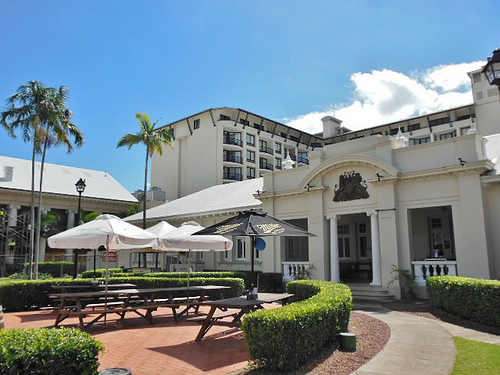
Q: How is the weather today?
A: It is clear.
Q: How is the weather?
A: It is clear.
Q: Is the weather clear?
A: Yes, it is clear.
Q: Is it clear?
A: Yes, it is clear.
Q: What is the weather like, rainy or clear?
A: It is clear.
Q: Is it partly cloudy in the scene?
A: No, it is clear.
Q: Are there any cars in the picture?
A: No, there are no cars.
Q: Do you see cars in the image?
A: No, there are no cars.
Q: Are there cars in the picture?
A: No, there are no cars.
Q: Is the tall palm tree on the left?
A: Yes, the palm is on the left of the image.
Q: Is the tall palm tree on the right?
A: No, the palm is on the left of the image.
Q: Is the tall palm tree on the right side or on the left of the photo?
A: The palm tree is on the left of the image.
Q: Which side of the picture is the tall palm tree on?
A: The palm is on the left of the image.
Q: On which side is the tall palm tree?
A: The palm is on the left of the image.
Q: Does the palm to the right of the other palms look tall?
A: Yes, the palm is tall.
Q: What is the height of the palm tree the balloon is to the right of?
A: The palm tree is tall.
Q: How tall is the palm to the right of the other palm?
A: The palm tree is tall.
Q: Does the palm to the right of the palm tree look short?
A: No, the palm is tall.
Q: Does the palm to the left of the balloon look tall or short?
A: The palm is tall.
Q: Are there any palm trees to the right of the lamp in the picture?
A: Yes, there is a palm tree to the right of the lamp.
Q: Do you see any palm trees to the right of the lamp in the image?
A: Yes, there is a palm tree to the right of the lamp.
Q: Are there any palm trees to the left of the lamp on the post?
A: No, the palm tree is to the right of the lamp.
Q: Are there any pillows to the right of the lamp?
A: No, there is a palm tree to the right of the lamp.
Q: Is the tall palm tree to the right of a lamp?
A: Yes, the palm is to the right of a lamp.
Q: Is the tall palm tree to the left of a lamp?
A: No, the palm is to the right of a lamp.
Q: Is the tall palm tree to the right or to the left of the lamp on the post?
A: The palm is to the right of the lamp.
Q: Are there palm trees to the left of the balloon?
A: Yes, there is a palm tree to the left of the balloon.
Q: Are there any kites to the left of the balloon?
A: No, there is a palm tree to the left of the balloon.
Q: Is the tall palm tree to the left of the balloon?
A: Yes, the palm is to the left of the balloon.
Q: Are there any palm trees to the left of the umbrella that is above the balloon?
A: Yes, there is a palm tree to the left of the umbrella.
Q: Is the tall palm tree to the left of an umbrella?
A: Yes, the palm tree is to the left of an umbrella.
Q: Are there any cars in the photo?
A: No, there are no cars.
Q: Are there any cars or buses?
A: No, there are no cars or buses.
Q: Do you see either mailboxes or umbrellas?
A: Yes, there is an umbrella.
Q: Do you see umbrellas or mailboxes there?
A: Yes, there is an umbrella.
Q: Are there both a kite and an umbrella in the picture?
A: No, there is an umbrella but no kites.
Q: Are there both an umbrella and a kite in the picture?
A: No, there is an umbrella but no kites.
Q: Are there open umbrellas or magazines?
A: Yes, there is an open umbrella.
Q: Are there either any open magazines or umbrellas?
A: Yes, there is an open umbrella.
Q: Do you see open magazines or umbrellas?
A: Yes, there is an open umbrella.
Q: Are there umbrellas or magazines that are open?
A: Yes, the umbrella is open.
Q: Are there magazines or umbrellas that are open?
A: Yes, the umbrella is open.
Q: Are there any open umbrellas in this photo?
A: Yes, there is an open umbrella.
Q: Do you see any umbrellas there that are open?
A: Yes, there is an umbrella that is open.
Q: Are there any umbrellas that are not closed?
A: Yes, there is a open umbrella.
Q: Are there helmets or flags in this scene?
A: No, there are no helmets or flags.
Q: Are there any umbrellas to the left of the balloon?
A: Yes, there is an umbrella to the left of the balloon.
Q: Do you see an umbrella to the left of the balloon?
A: Yes, there is an umbrella to the left of the balloon.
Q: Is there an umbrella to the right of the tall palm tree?
A: Yes, there is an umbrella to the right of the palm.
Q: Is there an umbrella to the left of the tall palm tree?
A: No, the umbrella is to the right of the palm.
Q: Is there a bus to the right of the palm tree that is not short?
A: No, there is an umbrella to the right of the palm.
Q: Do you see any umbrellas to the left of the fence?
A: Yes, there is an umbrella to the left of the fence.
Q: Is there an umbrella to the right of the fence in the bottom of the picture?
A: No, the umbrella is to the left of the fence.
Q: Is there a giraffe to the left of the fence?
A: No, there is an umbrella to the left of the fence.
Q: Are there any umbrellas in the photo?
A: Yes, there is an umbrella.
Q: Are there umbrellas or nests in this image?
A: Yes, there is an umbrella.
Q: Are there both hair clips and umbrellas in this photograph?
A: No, there is an umbrella but no hair clips.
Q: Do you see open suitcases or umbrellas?
A: Yes, there is an open umbrella.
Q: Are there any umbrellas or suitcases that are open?
A: Yes, the umbrella is open.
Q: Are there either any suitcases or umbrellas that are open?
A: Yes, the umbrella is open.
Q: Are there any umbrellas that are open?
A: Yes, there is an open umbrella.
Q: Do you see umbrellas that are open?
A: Yes, there is an umbrella that is open.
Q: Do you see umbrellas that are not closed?
A: Yes, there is a open umbrella.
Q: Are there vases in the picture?
A: No, there are no vases.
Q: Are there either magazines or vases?
A: No, there are no vases or magazines.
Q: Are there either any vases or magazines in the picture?
A: No, there are no vases or magazines.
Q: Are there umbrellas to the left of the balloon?
A: Yes, there is an umbrella to the left of the balloon.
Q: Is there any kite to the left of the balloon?
A: No, there is an umbrella to the left of the balloon.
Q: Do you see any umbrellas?
A: Yes, there is an umbrella.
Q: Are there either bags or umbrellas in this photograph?
A: Yes, there is an umbrella.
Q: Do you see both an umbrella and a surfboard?
A: No, there is an umbrella but no surfboards.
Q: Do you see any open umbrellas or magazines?
A: Yes, there is an open umbrella.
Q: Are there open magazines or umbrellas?
A: Yes, there is an open umbrella.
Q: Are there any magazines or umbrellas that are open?
A: Yes, the umbrella is open.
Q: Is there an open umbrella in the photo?
A: Yes, there is an open umbrella.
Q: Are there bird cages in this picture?
A: No, there are no bird cages.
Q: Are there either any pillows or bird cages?
A: No, there are no bird cages or pillows.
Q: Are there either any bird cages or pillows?
A: No, there are no bird cages or pillows.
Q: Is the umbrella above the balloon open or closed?
A: The umbrella is open.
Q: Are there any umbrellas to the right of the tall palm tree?
A: Yes, there is an umbrella to the right of the palm tree.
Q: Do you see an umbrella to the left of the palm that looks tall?
A: No, the umbrella is to the right of the palm.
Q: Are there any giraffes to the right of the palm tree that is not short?
A: No, there is an umbrella to the right of the palm.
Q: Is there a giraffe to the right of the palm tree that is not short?
A: No, there is an umbrella to the right of the palm.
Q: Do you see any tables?
A: Yes, there is a table.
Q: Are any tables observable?
A: Yes, there is a table.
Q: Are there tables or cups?
A: Yes, there is a table.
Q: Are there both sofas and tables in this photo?
A: No, there is a table but no sofas.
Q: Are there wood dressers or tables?
A: Yes, there is a wood table.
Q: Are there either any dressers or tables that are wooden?
A: Yes, the table is wooden.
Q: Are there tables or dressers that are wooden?
A: Yes, the table is wooden.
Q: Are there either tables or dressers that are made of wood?
A: Yes, the table is made of wood.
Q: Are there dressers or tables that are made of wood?
A: Yes, the table is made of wood.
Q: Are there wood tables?
A: Yes, there is a table that is made of wood.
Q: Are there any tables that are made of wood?
A: Yes, there is a table that is made of wood.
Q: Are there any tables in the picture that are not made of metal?
A: Yes, there is a table that is made of wood.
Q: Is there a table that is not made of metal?
A: Yes, there is a table that is made of wood.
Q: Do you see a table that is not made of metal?
A: Yes, there is a table that is made of wood.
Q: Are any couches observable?
A: No, there are no couches.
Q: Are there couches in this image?
A: No, there are no couches.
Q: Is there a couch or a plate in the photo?
A: No, there are no couches or plates.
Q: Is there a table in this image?
A: Yes, there is a table.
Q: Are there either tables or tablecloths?
A: Yes, there is a table.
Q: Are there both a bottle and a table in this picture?
A: No, there is a table but no bottles.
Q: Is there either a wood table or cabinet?
A: Yes, there is a wood table.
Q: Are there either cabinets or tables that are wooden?
A: Yes, the table is wooden.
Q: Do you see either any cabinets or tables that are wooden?
A: Yes, the table is wooden.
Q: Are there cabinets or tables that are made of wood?
A: Yes, the table is made of wood.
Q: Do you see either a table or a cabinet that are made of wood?
A: Yes, the table is made of wood.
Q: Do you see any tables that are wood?
A: Yes, there is a wood table.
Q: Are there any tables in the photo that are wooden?
A: Yes, there is a table that is wooden.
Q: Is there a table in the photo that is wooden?
A: Yes, there is a table that is wooden.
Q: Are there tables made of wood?
A: Yes, there is a table that is made of wood.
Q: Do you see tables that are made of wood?
A: Yes, there is a table that is made of wood.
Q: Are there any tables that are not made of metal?
A: Yes, there is a table that is made of wood.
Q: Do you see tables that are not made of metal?
A: Yes, there is a table that is made of wood.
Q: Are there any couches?
A: No, there are no couches.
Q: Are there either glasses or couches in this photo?
A: No, there are no couches or glasses.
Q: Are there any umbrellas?
A: Yes, there is an umbrella.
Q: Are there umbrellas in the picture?
A: Yes, there is an umbrella.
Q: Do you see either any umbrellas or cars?
A: Yes, there is an umbrella.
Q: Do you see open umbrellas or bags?
A: Yes, there is an open umbrella.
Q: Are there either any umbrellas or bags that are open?
A: Yes, the umbrella is open.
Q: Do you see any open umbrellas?
A: Yes, there is an open umbrella.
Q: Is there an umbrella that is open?
A: Yes, there is an umbrella that is open.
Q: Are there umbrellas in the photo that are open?
A: Yes, there is an umbrella that is open.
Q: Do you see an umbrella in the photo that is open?
A: Yes, there is an umbrella that is open.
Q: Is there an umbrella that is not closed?
A: Yes, there is a open umbrella.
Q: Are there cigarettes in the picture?
A: No, there are no cigarettes.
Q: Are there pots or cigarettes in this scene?
A: No, there are no cigarettes or pots.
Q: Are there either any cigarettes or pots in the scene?
A: No, there are no cigarettes or pots.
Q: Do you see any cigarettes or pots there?
A: No, there are no cigarettes or pots.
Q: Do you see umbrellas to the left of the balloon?
A: Yes, there is an umbrella to the left of the balloon.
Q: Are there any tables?
A: Yes, there is a table.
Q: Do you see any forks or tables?
A: Yes, there is a table.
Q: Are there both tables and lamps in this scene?
A: Yes, there are both a table and a lamp.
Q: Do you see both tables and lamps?
A: Yes, there are both a table and a lamp.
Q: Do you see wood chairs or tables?
A: Yes, there is a wood table.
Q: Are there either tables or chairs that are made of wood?
A: Yes, the table is made of wood.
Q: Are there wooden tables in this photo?
A: Yes, there is a wood table.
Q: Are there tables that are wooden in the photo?
A: Yes, there is a wood table.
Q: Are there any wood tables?
A: Yes, there is a wood table.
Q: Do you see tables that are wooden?
A: Yes, there is a table that is wooden.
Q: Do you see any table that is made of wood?
A: Yes, there is a table that is made of wood.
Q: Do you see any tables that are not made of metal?
A: Yes, there is a table that is made of wood.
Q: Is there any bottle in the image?
A: No, there are no bottles.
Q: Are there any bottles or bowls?
A: No, there are no bottles or bowls.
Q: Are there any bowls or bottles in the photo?
A: No, there are no bottles or bowls.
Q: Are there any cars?
A: No, there are no cars.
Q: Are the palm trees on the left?
A: Yes, the palm trees are on the left of the image.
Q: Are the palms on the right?
A: No, the palms are on the left of the image.